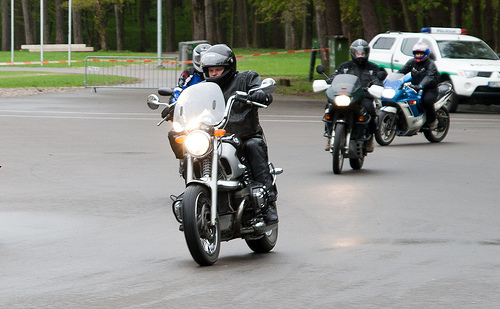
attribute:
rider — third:
[311, 38, 385, 173]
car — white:
[367, 26, 497, 117]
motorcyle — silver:
[148, 153, 298, 238]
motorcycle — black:
[310, 64, 375, 171]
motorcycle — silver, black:
[141, 80, 278, 263]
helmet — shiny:
[190, 41, 257, 109]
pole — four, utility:
[157, 0, 163, 71]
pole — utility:
[65, 0, 70, 67]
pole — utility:
[39, 0, 43, 63]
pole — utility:
[9, 0, 14, 63]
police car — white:
[364, 25, 499, 103]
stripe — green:
[372, 58, 409, 74]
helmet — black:
[194, 40, 241, 90]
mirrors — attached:
[146, 81, 283, 111]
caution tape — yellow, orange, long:
[18, 44, 323, 61]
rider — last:
[384, 37, 481, 144]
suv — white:
[365, 25, 497, 115]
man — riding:
[162, 42, 278, 221]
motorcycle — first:
[147, 85, 283, 265]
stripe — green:
[359, 60, 464, 82]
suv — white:
[344, 15, 498, 125]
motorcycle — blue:
[360, 37, 474, 155]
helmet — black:
[201, 46, 238, 78]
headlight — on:
[180, 125, 214, 157]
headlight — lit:
[181, 129, 211, 157]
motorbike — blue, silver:
[378, 67, 458, 144]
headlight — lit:
[174, 129, 235, 167]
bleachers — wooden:
[23, 25, 90, 64]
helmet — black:
[195, 41, 241, 81]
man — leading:
[190, 53, 282, 211]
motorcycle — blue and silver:
[369, 74, 456, 145]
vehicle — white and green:
[363, 16, 484, 101]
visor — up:
[199, 51, 227, 70]